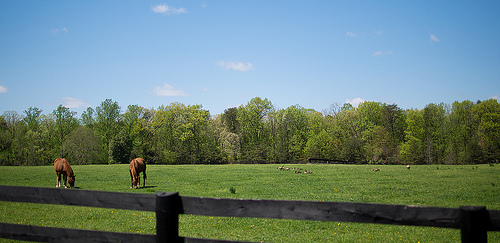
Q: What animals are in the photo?
A: Horses.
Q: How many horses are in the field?
A: Two.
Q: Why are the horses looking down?
A: They are eating.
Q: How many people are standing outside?
A: None.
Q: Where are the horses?
A: In a grassy field.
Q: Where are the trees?
A: Behind the horses.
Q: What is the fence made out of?
A: Wood.